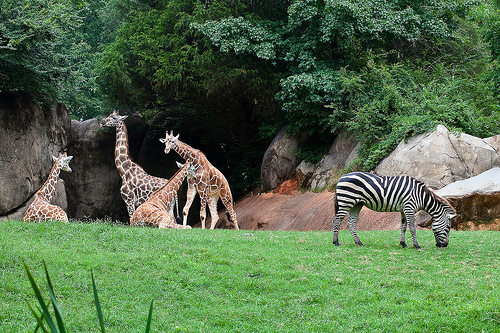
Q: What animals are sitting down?
A: Giraffes.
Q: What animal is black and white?
A: Zebra.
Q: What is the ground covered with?
A: Grass.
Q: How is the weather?
A: Clear.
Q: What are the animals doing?
A: Grazing.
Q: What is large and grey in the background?
A: Rocks.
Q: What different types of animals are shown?
A: Giraffes and a zebra.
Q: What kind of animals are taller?
A: Giraffes.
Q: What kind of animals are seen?
A: Giraffes and zebra.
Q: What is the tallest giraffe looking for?
A: Food.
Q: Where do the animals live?
A: Zoo.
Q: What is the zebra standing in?
A: Grass.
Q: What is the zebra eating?
A: Grass.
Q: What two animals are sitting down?
A: Giraffes.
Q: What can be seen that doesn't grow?
A: Rocks.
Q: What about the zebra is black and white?
A: Fur.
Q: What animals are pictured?
A: Zebra and giraffes.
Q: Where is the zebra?
A: On the grass.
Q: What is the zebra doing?
A: Eating.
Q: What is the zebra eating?
A: Grass.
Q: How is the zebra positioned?
A: Standing.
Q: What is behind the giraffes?
A: Trees.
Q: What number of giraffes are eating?
A: One.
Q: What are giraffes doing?
A: Sitting on grass.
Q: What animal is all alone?
A: Zebra.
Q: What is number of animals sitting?
A: Two.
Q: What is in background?
A: Green trees.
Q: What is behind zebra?
A: Rock structure.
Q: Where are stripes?
A: On a zebra.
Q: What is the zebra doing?
A: Grazing.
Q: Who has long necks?
A: The giraffe.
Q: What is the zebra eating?
A: Grass.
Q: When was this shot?
A: Daytime.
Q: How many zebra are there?
A: 1.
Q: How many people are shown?
A: 0.